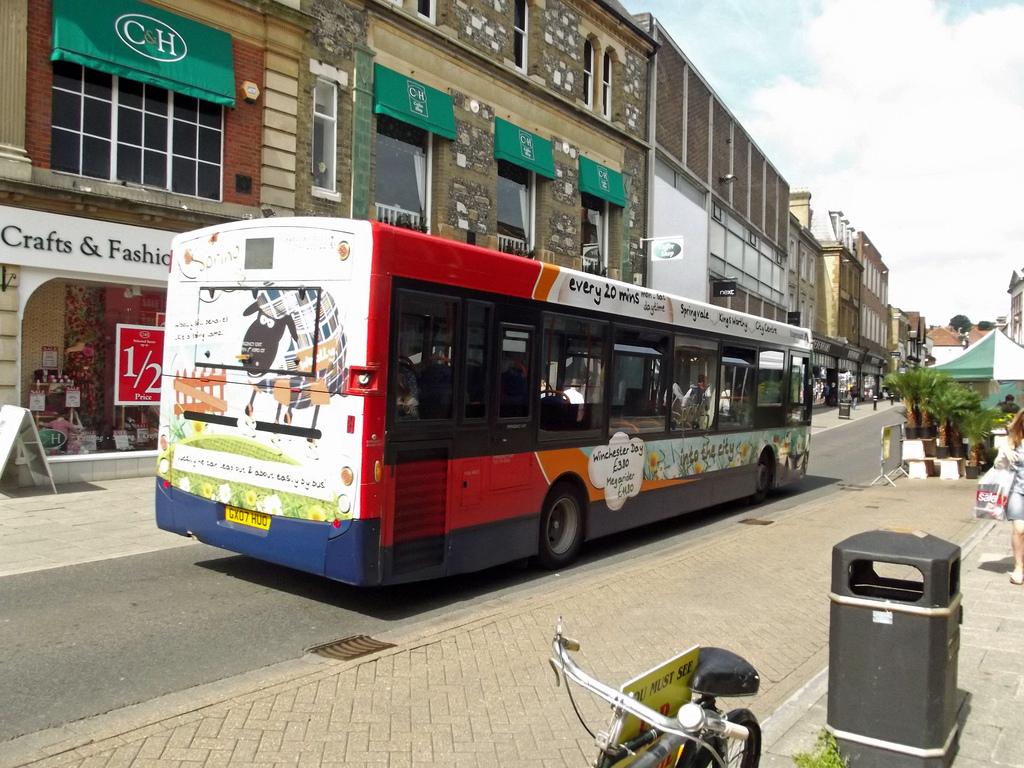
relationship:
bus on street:
[156, 219, 817, 587] [1, 394, 917, 762]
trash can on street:
[788, 526, 982, 767] [1, 394, 917, 762]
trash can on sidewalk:
[788, 526, 982, 767] [0, 466, 1022, 758]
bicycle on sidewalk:
[546, 604, 772, 764] [0, 466, 1022, 758]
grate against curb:
[314, 630, 394, 669] [0, 472, 882, 762]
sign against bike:
[613, 640, 704, 747] [539, 609, 818, 766]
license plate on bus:
[217, 473, 269, 549] [156, 219, 817, 587]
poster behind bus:
[113, 322, 164, 409] [156, 219, 817, 587]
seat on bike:
[684, 639, 758, 702] [544, 617, 773, 764]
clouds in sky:
[748, 4, 1020, 258] [622, 3, 1020, 326]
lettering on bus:
[563, 267, 803, 347] [134, 192, 828, 613]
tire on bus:
[535, 481, 596, 572] [156, 219, 817, 587]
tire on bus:
[760, 453, 789, 503] [156, 219, 817, 587]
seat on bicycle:
[684, 639, 758, 702] [689, 644, 765, 705]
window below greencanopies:
[53, 58, 116, 190] [51, 8, 630, 225]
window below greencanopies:
[108, 73, 176, 190] [51, 8, 630, 225]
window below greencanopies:
[164, 99, 231, 197] [51, 8, 630, 225]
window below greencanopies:
[377, 124, 425, 233] [51, 8, 630, 225]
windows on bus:
[398, 277, 814, 436] [156, 219, 817, 587]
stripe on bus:
[142, 466, 812, 607] [156, 219, 817, 587]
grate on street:
[314, 630, 395, 669] [1, 394, 917, 762]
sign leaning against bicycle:
[613, 640, 704, 748] [544, 628, 773, 763]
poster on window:
[114, 326, 165, 404] [12, 273, 170, 457]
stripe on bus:
[542, 304, 666, 438] [156, 219, 817, 587]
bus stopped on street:
[156, 219, 817, 587] [1, 394, 917, 762]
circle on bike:
[665, 670, 728, 768] [682, 694, 717, 740]